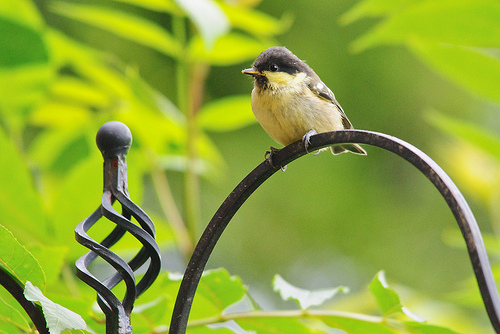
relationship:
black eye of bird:
[270, 64, 280, 71] [234, 43, 372, 160]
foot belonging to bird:
[259, 139, 290, 173] [240, 47, 368, 173]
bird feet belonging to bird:
[300, 130, 316, 157] [240, 47, 368, 173]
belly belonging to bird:
[250, 87, 310, 140] [240, 47, 368, 173]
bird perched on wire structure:
[234, 43, 372, 160] [165, 126, 481, 332]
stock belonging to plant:
[172, 19, 208, 245] [105, 3, 270, 203]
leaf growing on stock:
[0, 0, 500, 334] [172, 19, 208, 245]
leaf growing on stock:
[198, 94, 257, 131] [172, 19, 208, 245]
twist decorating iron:
[72, 185, 162, 315] [0, 121, 161, 334]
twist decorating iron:
[94, 185, 156, 315] [0, 121, 161, 334]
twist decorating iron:
[74, 197, 137, 313] [0, 121, 161, 334]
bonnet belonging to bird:
[254, 44, 302, 63] [240, 47, 368, 173]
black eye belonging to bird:
[267, 64, 279, 71] [240, 47, 368, 173]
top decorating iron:
[93, 118, 133, 158] [69, 137, 168, 324]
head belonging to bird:
[241, 46, 303, 82] [234, 43, 372, 160]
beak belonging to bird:
[242, 64, 257, 78] [241, 45, 363, 159]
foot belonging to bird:
[262, 145, 287, 172] [216, 27, 474, 170]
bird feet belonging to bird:
[300, 130, 316, 157] [216, 27, 474, 170]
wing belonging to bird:
[302, 67, 344, 112] [240, 47, 368, 173]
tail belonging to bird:
[331, 142, 365, 157] [239, 47, 369, 154]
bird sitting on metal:
[240, 47, 368, 173] [169, 128, 499, 331]